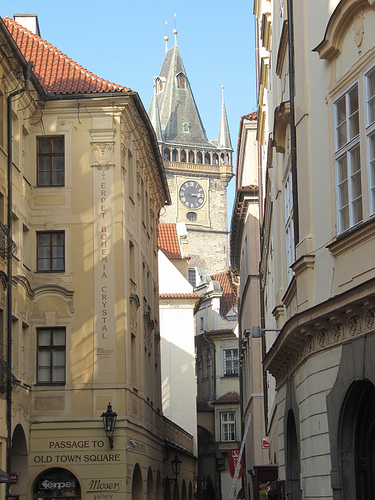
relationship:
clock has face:
[174, 177, 209, 212] [179, 180, 204, 209]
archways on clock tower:
[161, 146, 231, 169] [134, 13, 235, 270]